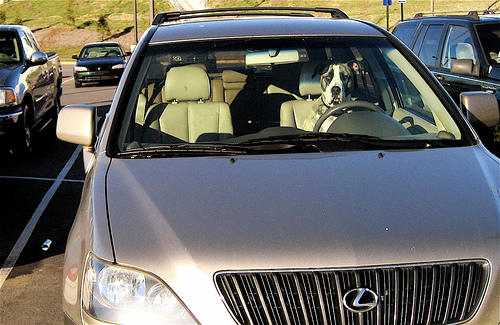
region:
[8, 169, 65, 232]
this is the ground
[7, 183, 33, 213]
the road is brown in color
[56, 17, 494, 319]
this is a car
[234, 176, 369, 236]
the car is grey in color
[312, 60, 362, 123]
this is a dog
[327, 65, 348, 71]
the dog is black and white in color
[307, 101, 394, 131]
this is the steering wheel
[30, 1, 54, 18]
this is the grass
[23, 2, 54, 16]
the grass is green in color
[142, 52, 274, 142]
this is a windscreen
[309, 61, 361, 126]
a dog sitting behind the steering wheel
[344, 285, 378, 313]
the lexus logo on the car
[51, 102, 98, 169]
the side view mirror of the car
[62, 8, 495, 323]
the svu in the parking lot with a dog in it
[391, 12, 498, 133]
a black svu parked next to the lexus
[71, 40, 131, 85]
the black car in the parking lot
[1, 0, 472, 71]
the hill next to the parking lot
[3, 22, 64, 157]
the black truck in the parking lot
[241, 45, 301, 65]
the rear view mirror of the car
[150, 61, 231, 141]
the passenger side seat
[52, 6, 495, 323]
a tan four door vehicle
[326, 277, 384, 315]
logo on front of vehicle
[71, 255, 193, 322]
front headlight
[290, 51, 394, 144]
dog sitting behind steering wheel inside vehicle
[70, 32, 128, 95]
small black car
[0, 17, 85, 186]
dark pickup truck in parking space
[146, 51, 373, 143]
tan seating in vehicle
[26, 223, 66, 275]
object on the ground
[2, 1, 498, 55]
grass on rising ground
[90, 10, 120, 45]
small green tree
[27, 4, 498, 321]
silver car parked in lot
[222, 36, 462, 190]
dog sitting behind steering wheel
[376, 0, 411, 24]
blue sign on post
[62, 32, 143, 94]
dark color car parked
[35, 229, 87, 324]
trash on ground by car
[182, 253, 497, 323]
front grill of car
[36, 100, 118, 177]
side mirror of car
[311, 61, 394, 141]
black and white dog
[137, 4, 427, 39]
luggage rack on top of car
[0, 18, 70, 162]
pickup truck parked in lot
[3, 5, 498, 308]
scene of a full parking lot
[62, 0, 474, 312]
a scene outside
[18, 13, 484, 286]
a scene during the day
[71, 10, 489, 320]
a silver car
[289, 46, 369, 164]
a dog in the driver seat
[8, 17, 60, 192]
a black truck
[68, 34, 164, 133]
a black car in the background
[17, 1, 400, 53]
field in the background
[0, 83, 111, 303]
a white line paint on the ground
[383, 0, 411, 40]
a blue and white sign in the background